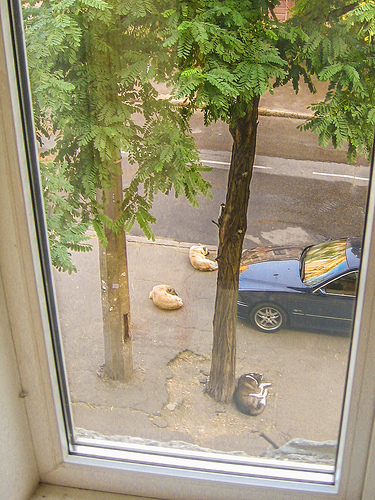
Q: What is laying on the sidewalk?
A: Dogs.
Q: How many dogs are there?
A: 3.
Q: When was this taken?
A: Daytime.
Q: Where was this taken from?
A: A window.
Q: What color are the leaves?
A: Green.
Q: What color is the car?
A: Blue.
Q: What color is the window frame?
A: White.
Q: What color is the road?
A: Black.